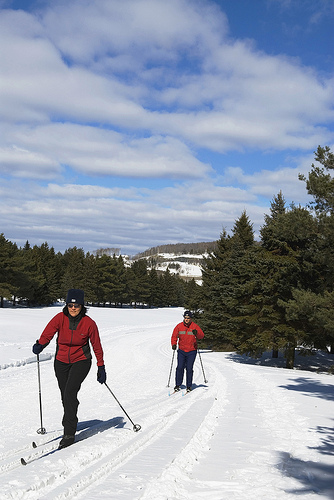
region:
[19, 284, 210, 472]
cross-country skiers following a path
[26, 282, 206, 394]
man skiing behind woman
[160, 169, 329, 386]
evergreen trees to side of skiers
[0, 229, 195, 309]
row of trees on other side of trail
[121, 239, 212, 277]
rows of trees across distant mountain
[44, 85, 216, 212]
greyish clouds over bright blue skies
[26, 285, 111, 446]
woman in dark cap, red jacket and black pants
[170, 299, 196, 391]
man in cap, red jacket, and dark pants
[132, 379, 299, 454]
smooth and rough snow alternating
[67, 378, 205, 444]
short shadows behind skiers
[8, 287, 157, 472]
woman on skis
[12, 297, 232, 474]
two people skiing on the snow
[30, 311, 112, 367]
red and black jacket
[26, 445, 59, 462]
snow on the skis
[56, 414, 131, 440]
woman's shadow on the ground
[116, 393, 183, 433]
tracks in the snow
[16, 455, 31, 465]
top of ski is bent upwards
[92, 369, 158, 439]
ski pole is diagonal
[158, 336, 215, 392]
two thin skin poles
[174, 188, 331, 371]
thick green trees with no snow on them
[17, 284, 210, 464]
two people skiing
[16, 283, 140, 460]
the woman is wearing a black hat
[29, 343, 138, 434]
the ski poles are black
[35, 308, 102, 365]
the woman is wearing a red coat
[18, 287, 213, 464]
the man is behind the woman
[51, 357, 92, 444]
the woman is wearing black pants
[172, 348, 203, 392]
the man is wearing blue pants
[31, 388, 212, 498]
the snow has tracks in it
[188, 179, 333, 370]
the trees are big and green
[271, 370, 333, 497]
shadows in the snow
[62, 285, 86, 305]
a black hat on a woman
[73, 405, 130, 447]
the shadow of a woman on the snow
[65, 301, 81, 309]
sunglasses on a woman's face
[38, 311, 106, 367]
a red jacket on a woman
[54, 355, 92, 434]
black pants on a woman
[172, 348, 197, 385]
navy pants on a man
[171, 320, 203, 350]
a red jacket with a gray stripe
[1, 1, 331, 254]
a blue and white cloudy sky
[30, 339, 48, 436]
a ski pole in a woman's hand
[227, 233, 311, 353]
pine tree near the snow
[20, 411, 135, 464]
a lady is using snowboard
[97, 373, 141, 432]
a lady holding ski pole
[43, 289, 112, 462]
a lady wearing snow suit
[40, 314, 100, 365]
a brown color jacket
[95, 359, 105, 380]
black color gloves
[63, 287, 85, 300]
a black color hat on the lady's head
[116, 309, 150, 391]
a place full of white snow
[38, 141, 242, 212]
a blue color sky with clouds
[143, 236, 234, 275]
mountain covered with snow